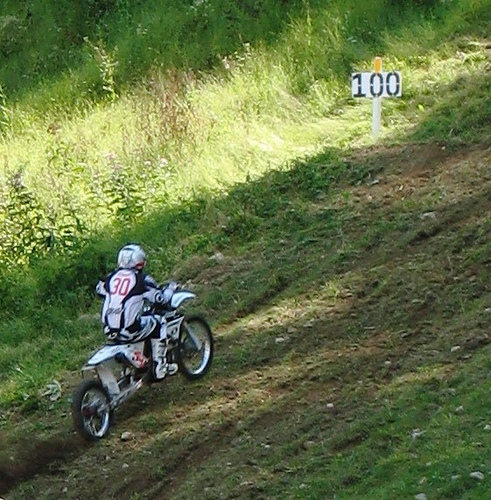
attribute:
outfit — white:
[91, 268, 182, 383]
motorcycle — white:
[70, 282, 215, 451]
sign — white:
[349, 56, 406, 142]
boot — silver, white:
[149, 319, 179, 381]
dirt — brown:
[158, 465, 187, 484]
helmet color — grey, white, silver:
[115, 244, 147, 270]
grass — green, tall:
[2, 5, 346, 159]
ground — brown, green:
[216, 148, 488, 498]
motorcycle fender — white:
[80, 346, 131, 372]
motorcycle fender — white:
[170, 290, 197, 308]